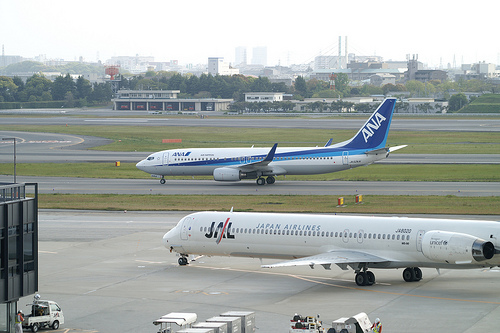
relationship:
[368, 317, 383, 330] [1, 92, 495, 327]
worker at airport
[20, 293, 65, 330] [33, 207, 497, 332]
truck on runway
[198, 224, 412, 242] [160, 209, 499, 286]
windows on plane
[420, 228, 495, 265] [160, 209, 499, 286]
engine on plane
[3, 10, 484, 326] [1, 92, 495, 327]
photograph taken airport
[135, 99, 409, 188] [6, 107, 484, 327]
plane on runway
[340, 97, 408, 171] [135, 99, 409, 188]
blue tail of plane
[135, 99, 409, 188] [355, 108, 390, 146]
plane with letters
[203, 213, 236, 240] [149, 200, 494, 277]
logo on plane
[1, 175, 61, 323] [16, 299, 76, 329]
luggage loading truck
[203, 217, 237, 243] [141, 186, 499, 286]
writing on plane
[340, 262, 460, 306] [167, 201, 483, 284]
wheels on airplane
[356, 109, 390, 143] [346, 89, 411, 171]
letters on tail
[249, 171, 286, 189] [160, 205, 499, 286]
wheel on airplane